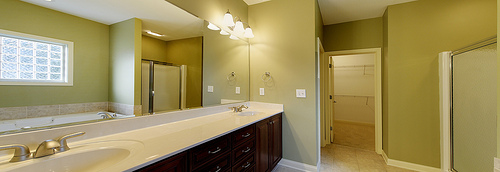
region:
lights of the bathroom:
[218, 5, 255, 39]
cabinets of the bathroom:
[174, 113, 284, 170]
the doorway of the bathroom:
[327, 45, 381, 150]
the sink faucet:
[0, 129, 86, 154]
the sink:
[7, 130, 136, 170]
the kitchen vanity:
[1, 98, 283, 170]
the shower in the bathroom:
[138, 53, 188, 114]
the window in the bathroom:
[1, 30, 70, 82]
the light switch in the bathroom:
[296, 88, 306, 97]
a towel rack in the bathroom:
[263, 70, 273, 85]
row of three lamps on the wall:
[218, 7, 257, 42]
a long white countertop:
[2, 98, 286, 170]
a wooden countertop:
[119, 110, 284, 170]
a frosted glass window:
[2, 30, 77, 87]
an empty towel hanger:
[258, 65, 280, 86]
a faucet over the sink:
[0, 126, 89, 163]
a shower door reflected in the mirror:
[140, 52, 192, 111]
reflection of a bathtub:
[1, 102, 132, 137]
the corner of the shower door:
[436, 33, 498, 169]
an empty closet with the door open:
[316, 35, 383, 154]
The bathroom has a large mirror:
[5, 5, 262, 122]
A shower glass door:
[437, 29, 497, 167]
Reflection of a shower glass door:
[140, 48, 209, 106]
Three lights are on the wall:
[215, 6, 254, 43]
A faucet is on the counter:
[0, 120, 92, 168]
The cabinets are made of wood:
[167, 115, 285, 167]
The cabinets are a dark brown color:
[150, 107, 285, 167]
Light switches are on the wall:
[290, 83, 310, 98]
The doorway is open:
[318, 30, 385, 164]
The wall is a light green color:
[392, 17, 430, 159]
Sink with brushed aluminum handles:
[223, 96, 258, 126]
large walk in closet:
[324, 50, 405, 165]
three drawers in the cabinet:
[226, 113, 289, 168]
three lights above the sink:
[221, 10, 257, 42]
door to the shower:
[425, 38, 497, 167]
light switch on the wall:
[292, 85, 302, 105]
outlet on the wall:
[256, 82, 272, 102]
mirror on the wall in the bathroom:
[7, 32, 82, 88]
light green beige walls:
[251, 10, 304, 121]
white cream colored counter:
[91, 111, 274, 156]